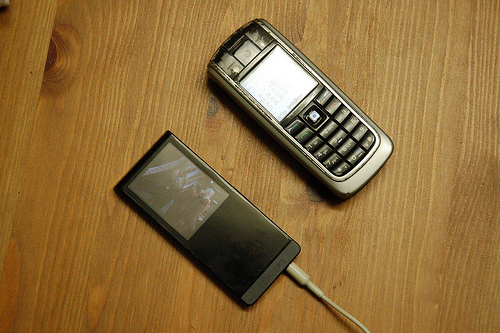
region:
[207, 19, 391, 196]
black nokia cellphone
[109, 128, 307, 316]
black ipod mini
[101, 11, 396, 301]
two black electronic devices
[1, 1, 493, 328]
brown wooden table in the back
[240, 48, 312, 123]
lighted screen of a mobile device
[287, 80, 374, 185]
keyboard of a nokia cellphone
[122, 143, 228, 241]
lighted screen of a black ipod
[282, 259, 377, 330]
white Charger Cable in the black ipod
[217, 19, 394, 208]
mobile device with a lighted screen and a keyboard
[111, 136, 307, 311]
ipod mini with no visible keyboard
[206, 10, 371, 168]
this is a cell phone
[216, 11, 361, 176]
the phone is old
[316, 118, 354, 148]
the buttons are black in color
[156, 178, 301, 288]
this is an ipad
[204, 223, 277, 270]
the ipad is black in color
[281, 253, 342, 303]
this is a cable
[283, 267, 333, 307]
the cable is white in color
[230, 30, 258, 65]
the phone is black in color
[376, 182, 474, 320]
the table is wooden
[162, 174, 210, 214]
the ipad is on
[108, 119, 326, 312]
Ipod on a table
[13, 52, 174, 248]
Brown on a desk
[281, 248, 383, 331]
White cord on an ipod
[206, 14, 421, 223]
Phone on a table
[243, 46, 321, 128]
Screen on a phone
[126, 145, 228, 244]
Screen on an ipod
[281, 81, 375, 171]
Buttons on a phone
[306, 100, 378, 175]
Black buttons on a phone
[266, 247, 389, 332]
White charging cord on an ipod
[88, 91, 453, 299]
Brown surface made of wood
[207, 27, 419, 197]
a small old mobile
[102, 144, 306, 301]
a small new mobile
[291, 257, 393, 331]
a small wire of charger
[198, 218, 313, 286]
black part of mobile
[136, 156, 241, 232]
the screen of mobile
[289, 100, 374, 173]
key pad of the mobile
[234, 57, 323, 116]
a white screen of the mobile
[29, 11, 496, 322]
a brown wooden table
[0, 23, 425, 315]
two mobile placed on table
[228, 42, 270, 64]
top part of mobile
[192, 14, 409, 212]
an old cell phone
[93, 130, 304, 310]
an old black video player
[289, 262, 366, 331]
a gray charging cable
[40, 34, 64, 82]
a knothole pattern in a wooden table top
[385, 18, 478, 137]
a brown wood table top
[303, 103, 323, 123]
a silver button in the center of a cell phone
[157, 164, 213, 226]
a video playing on a small screen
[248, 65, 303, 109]
numbers displayed on a cell phone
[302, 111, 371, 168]
black buttons on the face of a cell phone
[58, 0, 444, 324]
two electronic devices on a table